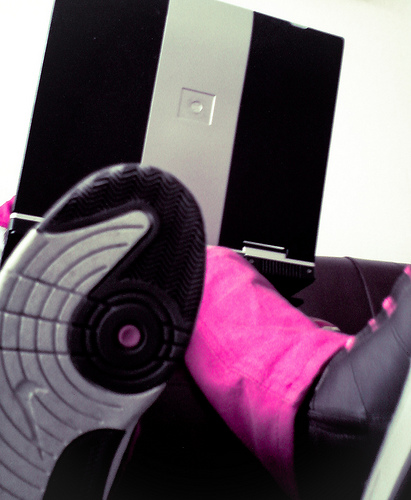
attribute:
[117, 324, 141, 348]
dot — pink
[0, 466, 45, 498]
lines — small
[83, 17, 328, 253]
computer — black, gray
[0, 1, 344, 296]
laptop — black , silver 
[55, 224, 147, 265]
lines — small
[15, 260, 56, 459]
lines — small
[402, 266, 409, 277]
lace — pink 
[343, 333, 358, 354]
lace — pink 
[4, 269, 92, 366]
lines — small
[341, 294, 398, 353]
laces — pink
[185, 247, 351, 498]
pants — pink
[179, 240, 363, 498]
leg — pink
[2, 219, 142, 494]
lines — small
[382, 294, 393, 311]
lace — pink 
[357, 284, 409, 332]
lace — pink 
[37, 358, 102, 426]
line — small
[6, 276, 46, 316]
line — small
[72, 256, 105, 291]
line — small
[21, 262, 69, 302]
line — small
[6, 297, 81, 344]
line — small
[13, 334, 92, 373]
line — small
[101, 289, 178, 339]
line — small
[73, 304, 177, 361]
line — small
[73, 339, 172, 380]
line — small